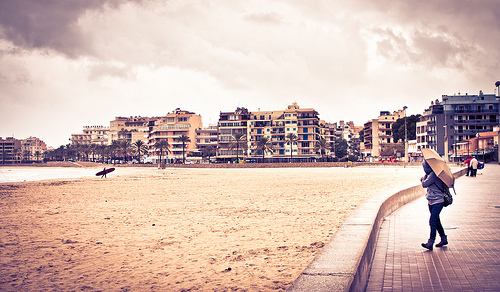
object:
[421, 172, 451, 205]
sweater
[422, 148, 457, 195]
gray umbrella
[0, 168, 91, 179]
water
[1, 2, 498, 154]
sky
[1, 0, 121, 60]
cloud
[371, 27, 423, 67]
cloud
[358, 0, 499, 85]
cloud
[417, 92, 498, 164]
building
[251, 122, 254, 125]
window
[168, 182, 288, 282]
floor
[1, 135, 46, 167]
building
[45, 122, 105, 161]
building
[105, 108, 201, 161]
building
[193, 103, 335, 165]
building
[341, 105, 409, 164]
building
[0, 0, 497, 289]
scene